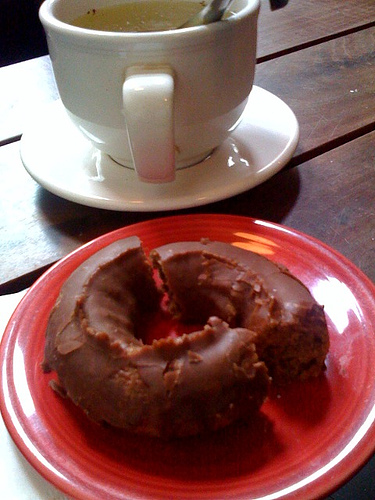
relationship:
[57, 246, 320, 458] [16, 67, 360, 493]
donut in foreground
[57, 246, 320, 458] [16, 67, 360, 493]
donut on plate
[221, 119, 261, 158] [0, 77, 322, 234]
light off plate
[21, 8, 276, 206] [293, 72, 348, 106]
cup and table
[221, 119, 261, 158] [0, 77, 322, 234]
light on plate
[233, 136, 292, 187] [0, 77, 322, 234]
reflection in plate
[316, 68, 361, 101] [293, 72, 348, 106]
dirt on table